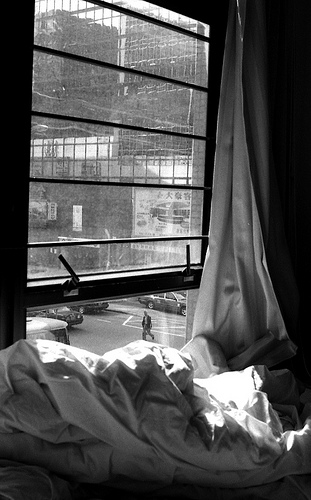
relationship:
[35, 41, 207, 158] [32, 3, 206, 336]
white pane in window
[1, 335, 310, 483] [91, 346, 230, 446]
blanket wadded lamp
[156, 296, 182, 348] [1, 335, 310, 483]
sun shining on blanket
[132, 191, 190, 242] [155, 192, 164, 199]
billboard with writing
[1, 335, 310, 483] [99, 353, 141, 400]
blanket has wrinkle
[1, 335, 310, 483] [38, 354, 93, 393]
blanket has wrinkle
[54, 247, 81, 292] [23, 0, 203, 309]
handle on window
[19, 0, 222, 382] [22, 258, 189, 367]
window overlooking street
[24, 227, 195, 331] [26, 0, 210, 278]
view out of window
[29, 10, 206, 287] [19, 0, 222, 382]
pane on window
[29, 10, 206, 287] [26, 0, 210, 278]
pane on window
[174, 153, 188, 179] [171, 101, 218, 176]
pane in window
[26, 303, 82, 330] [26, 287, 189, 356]
car driving in road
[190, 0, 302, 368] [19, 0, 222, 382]
curtain on window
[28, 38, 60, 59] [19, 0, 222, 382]
pane in window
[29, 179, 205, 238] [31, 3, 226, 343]
pane in window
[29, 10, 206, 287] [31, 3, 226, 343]
pane in window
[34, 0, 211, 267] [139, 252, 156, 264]
wall and chairs